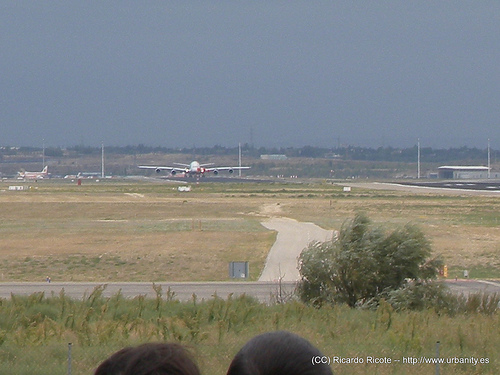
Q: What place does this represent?
A: It represents the airport.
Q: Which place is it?
A: It is an airport.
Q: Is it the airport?
A: Yes, it is the airport.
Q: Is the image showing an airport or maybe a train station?
A: It is showing an airport.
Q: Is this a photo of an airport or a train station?
A: It is showing an airport.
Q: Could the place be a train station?
A: No, it is an airport.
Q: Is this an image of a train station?
A: No, the picture is showing an airport.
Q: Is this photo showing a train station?
A: No, the picture is showing an airport.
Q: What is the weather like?
A: It is overcast.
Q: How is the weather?
A: It is overcast.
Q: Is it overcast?
A: Yes, it is overcast.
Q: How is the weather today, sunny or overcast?
A: It is overcast.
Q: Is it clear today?
A: No, it is overcast.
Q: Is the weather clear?
A: No, it is overcast.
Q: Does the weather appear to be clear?
A: No, it is overcast.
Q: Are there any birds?
A: No, there are no birds.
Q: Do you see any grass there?
A: Yes, there is grass.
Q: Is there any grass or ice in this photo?
A: Yes, there is grass.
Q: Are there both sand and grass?
A: No, there is grass but no sand.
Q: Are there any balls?
A: No, there are no balls.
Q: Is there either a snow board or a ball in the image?
A: No, there are no balls or snowboards.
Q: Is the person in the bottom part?
A: Yes, the person is in the bottom of the image.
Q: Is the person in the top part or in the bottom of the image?
A: The person is in the bottom of the image.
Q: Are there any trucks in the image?
A: No, there are no trucks.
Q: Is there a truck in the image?
A: No, there are no trucks.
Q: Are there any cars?
A: No, there are no cars.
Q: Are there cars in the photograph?
A: No, there are no cars.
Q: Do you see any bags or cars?
A: No, there are no cars or bags.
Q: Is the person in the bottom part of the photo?
A: Yes, the person is in the bottom of the image.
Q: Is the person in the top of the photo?
A: No, the person is in the bottom of the image.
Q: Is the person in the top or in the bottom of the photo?
A: The person is in the bottom of the image.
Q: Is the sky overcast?
A: Yes, the sky is overcast.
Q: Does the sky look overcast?
A: Yes, the sky is overcast.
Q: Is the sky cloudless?
A: No, the sky is overcast.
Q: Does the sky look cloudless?
A: No, the sky is overcast.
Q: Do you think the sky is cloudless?
A: No, the sky is overcast.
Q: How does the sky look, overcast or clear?
A: The sky is overcast.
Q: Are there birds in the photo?
A: No, there are no birds.